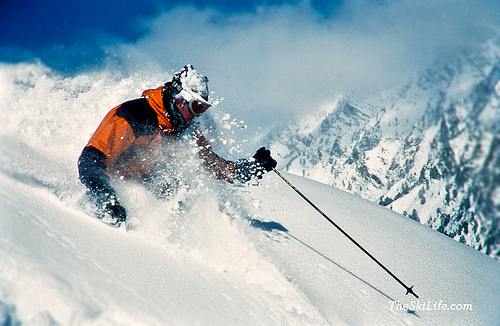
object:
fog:
[60, 0, 498, 150]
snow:
[7, 63, 498, 322]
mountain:
[1, 125, 499, 325]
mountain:
[230, 19, 499, 261]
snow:
[240, 26, 499, 261]